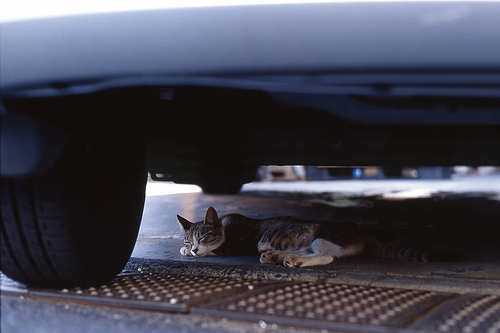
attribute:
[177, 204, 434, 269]
cat — sleeping, brown, white, asleep, striped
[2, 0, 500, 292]
car — stripes, parked, metal, white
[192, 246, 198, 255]
nose — black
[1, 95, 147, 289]
tire — black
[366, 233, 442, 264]
tail — striped, black, brown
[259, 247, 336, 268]
feet — black, white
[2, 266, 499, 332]
steel grate — metal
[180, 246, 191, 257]
paw — white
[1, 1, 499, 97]
bumper — blue